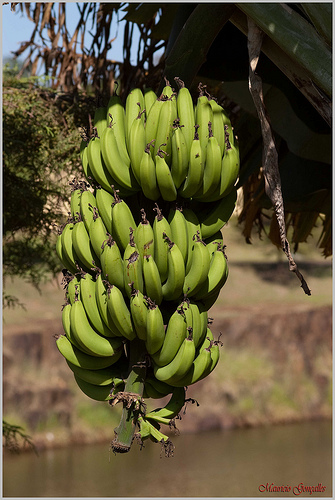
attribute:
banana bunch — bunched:
[86, 78, 240, 202]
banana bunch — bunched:
[52, 188, 230, 292]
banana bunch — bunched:
[54, 280, 221, 435]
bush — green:
[267, 382, 292, 403]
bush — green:
[220, 352, 266, 379]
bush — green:
[229, 394, 257, 414]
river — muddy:
[69, 453, 264, 491]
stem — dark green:
[110, 367, 143, 454]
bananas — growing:
[47, 75, 241, 461]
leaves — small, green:
[11, 101, 72, 194]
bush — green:
[13, 77, 82, 188]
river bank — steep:
[3, 303, 332, 450]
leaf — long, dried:
[242, 43, 328, 309]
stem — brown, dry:
[128, 280, 137, 297]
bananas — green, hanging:
[54, 77, 247, 447]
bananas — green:
[52, 82, 245, 414]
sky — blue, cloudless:
[1, 5, 152, 65]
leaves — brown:
[10, 2, 156, 86]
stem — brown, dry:
[213, 332, 224, 348]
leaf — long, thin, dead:
[246, 27, 311, 295]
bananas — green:
[65, 70, 252, 203]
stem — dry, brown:
[120, 376, 128, 383]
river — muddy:
[7, 429, 332, 497]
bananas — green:
[52, 58, 234, 397]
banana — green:
[160, 311, 183, 361]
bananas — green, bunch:
[25, 56, 280, 421]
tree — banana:
[221, 15, 323, 88]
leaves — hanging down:
[4, 3, 172, 97]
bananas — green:
[137, 113, 177, 146]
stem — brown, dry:
[139, 207, 152, 225]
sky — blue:
[2, 11, 28, 42]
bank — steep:
[221, 312, 324, 421]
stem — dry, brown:
[117, 390, 142, 407]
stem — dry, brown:
[173, 77, 188, 90]